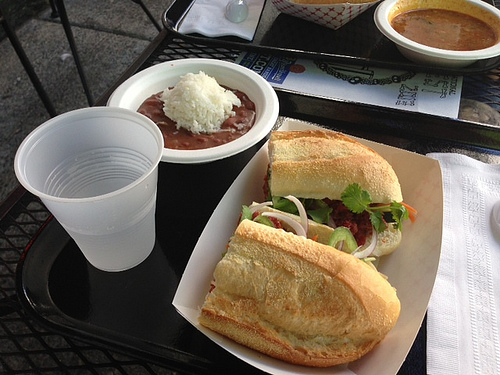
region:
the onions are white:
[272, 189, 307, 239]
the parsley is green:
[338, 183, 402, 229]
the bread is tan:
[237, 234, 390, 357]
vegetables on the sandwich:
[275, 145, 404, 253]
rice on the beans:
[160, 77, 237, 136]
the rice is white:
[167, 75, 225, 147]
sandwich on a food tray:
[211, 119, 407, 355]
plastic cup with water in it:
[24, 135, 165, 277]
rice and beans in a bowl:
[113, 58, 280, 163]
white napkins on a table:
[428, 142, 498, 319]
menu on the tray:
[228, 47, 470, 129]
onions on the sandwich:
[244, 198, 400, 272]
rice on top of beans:
[158, 73, 230, 130]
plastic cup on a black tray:
[13, 96, 172, 303]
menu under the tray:
[225, 34, 480, 124]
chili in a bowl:
[376, 7, 498, 76]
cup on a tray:
[12, 103, 144, 276]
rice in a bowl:
[170, 75, 250, 128]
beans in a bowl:
[176, 130, 204, 148]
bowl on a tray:
[175, 55, 275, 135]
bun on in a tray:
[196, 245, 322, 327]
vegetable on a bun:
[265, 200, 316, 233]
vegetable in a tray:
[350, 202, 400, 245]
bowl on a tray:
[416, 35, 491, 88]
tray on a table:
[380, 93, 491, 143]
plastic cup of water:
[6, 99, 203, 301]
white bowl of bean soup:
[105, 61, 285, 176]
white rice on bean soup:
[147, 69, 253, 136]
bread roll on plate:
[197, 211, 414, 373]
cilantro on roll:
[328, 172, 416, 256]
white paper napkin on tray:
[424, 144, 499, 374]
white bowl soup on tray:
[357, 0, 499, 72]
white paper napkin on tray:
[176, 0, 274, 52]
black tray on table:
[4, 60, 499, 373]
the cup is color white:
[7, 102, 168, 283]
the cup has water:
[9, 100, 171, 277]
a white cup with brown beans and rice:
[107, 52, 285, 170]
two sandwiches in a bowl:
[164, 112, 454, 372]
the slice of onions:
[259, 188, 316, 239]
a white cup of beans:
[374, 2, 499, 68]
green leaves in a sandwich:
[331, 180, 413, 236]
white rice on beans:
[156, 60, 243, 139]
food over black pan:
[8, 51, 494, 373]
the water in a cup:
[14, 98, 167, 288]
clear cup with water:
[13, 92, 173, 289]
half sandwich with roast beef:
[267, 129, 415, 244]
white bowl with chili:
[110, 48, 272, 159]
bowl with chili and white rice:
[117, 52, 266, 164]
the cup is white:
[13, 103, 163, 273]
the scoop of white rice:
[158, 70, 240, 132]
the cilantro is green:
[343, 183, 408, 230]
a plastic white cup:
[8, 103, 170, 291]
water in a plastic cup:
[13, 98, 167, 287]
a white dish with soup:
[367, 4, 499, 71]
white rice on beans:
[151, 63, 245, 144]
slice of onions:
[264, 188, 314, 238]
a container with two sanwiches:
[167, 108, 459, 368]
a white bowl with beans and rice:
[101, 47, 287, 176]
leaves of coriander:
[328, 173, 411, 235]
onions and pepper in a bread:
[238, 182, 390, 298]